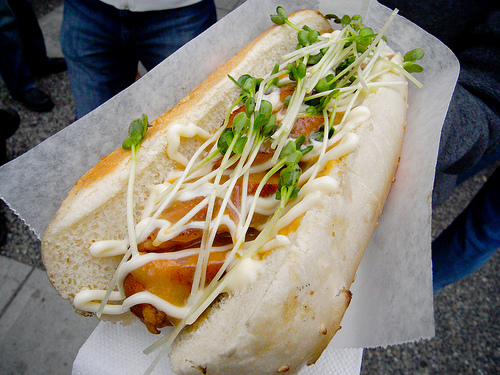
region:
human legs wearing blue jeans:
[433, 122, 498, 307]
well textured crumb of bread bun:
[44, 213, 89, 285]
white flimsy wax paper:
[356, 272, 427, 340]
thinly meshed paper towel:
[88, 333, 140, 374]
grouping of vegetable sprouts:
[289, 17, 424, 109]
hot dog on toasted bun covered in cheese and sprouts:
[44, 8, 411, 374]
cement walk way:
[1, 258, 40, 335]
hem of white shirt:
[95, 0, 206, 12]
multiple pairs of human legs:
[1, 3, 207, 133]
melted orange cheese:
[141, 262, 195, 297]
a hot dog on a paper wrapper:
[41, 8, 408, 373]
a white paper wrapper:
[0, 0, 461, 344]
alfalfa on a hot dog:
[98, 4, 425, 374]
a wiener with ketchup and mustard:
[122, 80, 326, 337]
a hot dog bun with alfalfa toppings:
[41, 7, 408, 373]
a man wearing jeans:
[61, 0, 219, 117]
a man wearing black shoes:
[14, 57, 66, 113]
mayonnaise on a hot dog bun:
[71, 105, 370, 313]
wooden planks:
[0, 255, 98, 372]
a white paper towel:
[69, 312, 363, 372]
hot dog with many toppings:
[103, 20, 402, 282]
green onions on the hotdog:
[225, 35, 356, 172]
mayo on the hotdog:
[62, 123, 279, 310]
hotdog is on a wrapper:
[70, 35, 437, 313]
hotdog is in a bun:
[117, 25, 374, 260]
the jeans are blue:
[45, 0, 200, 77]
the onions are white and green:
[180, 13, 406, 185]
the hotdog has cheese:
[154, 271, 195, 293]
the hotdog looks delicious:
[65, 20, 412, 313]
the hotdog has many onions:
[111, 40, 401, 284]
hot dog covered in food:
[65, 5, 432, 323]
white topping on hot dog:
[215, 133, 340, 250]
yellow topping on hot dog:
[151, 238, 209, 303]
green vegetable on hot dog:
[104, 99, 158, 237]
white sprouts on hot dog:
[261, 32, 336, 143]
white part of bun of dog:
[278, 172, 402, 310]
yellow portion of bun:
[164, 75, 215, 115]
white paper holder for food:
[350, 206, 448, 373]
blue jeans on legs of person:
[60, 5, 211, 99]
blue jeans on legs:
[441, 193, 485, 290]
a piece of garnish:
[114, 113, 151, 248]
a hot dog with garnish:
[38, 9, 435, 373]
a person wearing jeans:
[59, 1, 221, 121]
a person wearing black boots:
[14, 54, 76, 112]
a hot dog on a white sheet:
[1, 1, 466, 373]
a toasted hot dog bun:
[35, 9, 412, 373]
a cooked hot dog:
[37, 7, 409, 372]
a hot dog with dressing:
[35, 9, 417, 374]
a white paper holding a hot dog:
[0, 0, 462, 374]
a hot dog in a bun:
[123, 39, 363, 331]